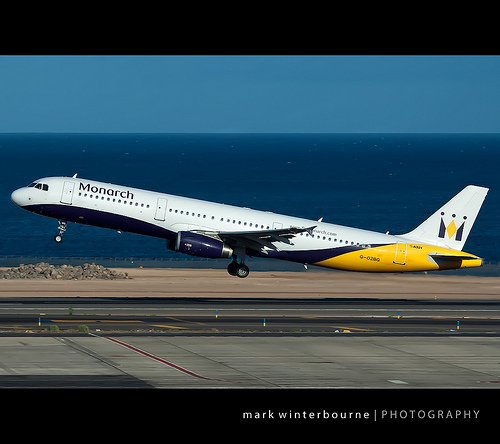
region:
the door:
[397, 241, 407, 266]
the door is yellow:
[394, 239, 407, 266]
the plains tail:
[418, 184, 486, 248]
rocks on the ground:
[7, 263, 109, 280]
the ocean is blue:
[185, 130, 400, 195]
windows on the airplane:
[170, 206, 208, 221]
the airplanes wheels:
[225, 260, 250, 278]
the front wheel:
[50, 233, 61, 243]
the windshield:
[35, 180, 50, 191]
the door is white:
[154, 195, 170, 223]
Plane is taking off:
[7, 168, 491, 298]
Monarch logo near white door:
[75, 180, 138, 200]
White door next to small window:
[150, 195, 170, 223]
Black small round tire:
[235, 260, 250, 277]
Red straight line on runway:
[102, 333, 222, 383]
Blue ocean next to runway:
[0, 130, 499, 267]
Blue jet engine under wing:
[172, 225, 234, 262]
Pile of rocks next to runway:
[0, 259, 132, 282]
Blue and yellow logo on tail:
[435, 208, 471, 245]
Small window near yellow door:
[367, 241, 372, 254]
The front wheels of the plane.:
[49, 223, 77, 243]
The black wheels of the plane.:
[225, 251, 250, 285]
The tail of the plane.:
[417, 174, 488, 244]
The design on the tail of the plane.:
[435, 207, 470, 246]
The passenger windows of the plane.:
[74, 185, 388, 257]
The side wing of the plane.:
[219, 210, 323, 253]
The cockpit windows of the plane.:
[32, 179, 52, 189]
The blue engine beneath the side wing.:
[174, 226, 236, 260]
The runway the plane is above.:
[21, 296, 497, 402]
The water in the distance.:
[3, 131, 496, 258]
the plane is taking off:
[16, 161, 497, 298]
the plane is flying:
[7, 168, 498, 295]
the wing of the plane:
[158, 213, 342, 245]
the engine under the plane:
[164, 232, 240, 264]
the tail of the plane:
[409, 177, 499, 286]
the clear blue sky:
[118, 79, 308, 107]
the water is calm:
[224, 145, 360, 192]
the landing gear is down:
[40, 218, 267, 290]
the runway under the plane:
[51, 332, 436, 396]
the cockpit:
[27, 179, 56, 194]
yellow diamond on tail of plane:
[447, 216, 457, 242]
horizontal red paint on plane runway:
[87, 328, 218, 383]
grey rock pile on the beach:
[3, 263, 133, 280]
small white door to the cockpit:
[60, 175, 77, 211]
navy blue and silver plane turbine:
[175, 230, 232, 258]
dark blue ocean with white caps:
[70, 131, 163, 174]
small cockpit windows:
[29, 180, 49, 189]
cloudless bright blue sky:
[0, 57, 498, 135]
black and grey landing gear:
[226, 257, 251, 279]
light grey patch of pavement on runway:
[383, 372, 410, 390]